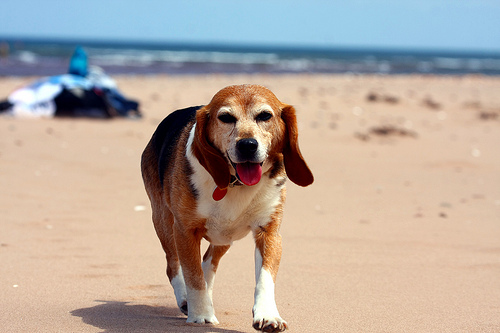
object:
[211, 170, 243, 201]
tag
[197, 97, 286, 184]
neck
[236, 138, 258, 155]
nose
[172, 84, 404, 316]
dog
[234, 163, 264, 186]
tongue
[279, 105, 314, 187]
ear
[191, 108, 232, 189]
ear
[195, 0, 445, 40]
sky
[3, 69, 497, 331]
sandy beach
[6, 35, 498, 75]
ocean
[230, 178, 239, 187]
collar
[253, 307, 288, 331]
foot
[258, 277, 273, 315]
fur